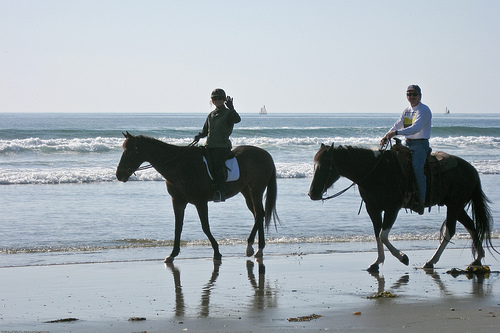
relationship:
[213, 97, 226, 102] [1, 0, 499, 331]
eyeglasses in photo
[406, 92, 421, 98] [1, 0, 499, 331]
eyeglasses in photo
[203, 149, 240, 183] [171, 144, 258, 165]
mat on horse back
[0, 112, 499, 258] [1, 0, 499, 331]
water in photo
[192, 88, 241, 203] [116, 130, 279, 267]
woman riding a horse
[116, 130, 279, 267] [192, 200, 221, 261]
horse has leg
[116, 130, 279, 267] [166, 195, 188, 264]
horse has leg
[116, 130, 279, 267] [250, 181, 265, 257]
horse has leg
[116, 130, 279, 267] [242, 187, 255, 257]
horse has leg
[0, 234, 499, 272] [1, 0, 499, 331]
coastline in photo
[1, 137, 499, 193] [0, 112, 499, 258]
waves in ocean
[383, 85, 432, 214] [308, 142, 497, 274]
man on horse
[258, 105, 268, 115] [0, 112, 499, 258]
boat in ocean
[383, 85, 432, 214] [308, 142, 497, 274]
man riding horse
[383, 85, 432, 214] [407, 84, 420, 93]
man wearing baseball cap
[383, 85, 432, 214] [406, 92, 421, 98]
man wearing eyeglasses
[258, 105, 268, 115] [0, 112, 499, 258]
boat in water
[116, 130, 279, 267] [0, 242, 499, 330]
horse on beach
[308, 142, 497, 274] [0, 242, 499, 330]
horse on beach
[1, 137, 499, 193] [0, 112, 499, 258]
waves in water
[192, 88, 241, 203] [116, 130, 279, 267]
woman riding horse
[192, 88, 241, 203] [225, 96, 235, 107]
woman holding up hand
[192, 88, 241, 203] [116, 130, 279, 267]
person on horse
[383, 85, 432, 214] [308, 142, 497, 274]
person on horse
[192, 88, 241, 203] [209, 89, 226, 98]
woman with helmet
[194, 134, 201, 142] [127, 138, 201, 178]
hand on horse reign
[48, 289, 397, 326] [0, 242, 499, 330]
tracks in sand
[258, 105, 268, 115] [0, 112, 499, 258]
boat on water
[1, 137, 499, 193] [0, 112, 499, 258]
waves in sea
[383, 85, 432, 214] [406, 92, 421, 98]
man wearing goggles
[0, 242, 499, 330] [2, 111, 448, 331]
sand in beach